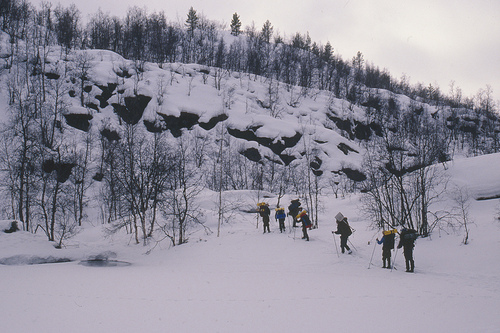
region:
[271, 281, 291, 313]
The snow is a very, very bright white color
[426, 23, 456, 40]
The sky is a rather dull gray color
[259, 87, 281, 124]
The rocks beneath the snow are dark brown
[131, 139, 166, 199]
The trees are a very deep brown color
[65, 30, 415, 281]
This whole photo was taken in Colorado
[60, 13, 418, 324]
This whole photo was taken in Denver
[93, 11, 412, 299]
This whole photo was taken in early afternoon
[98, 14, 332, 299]
These people signed up for this journey months ago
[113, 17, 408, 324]
Jackson Zeke is the man who took this photo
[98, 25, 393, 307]
This photo will soon appear in a tourist brochure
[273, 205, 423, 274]
these are people walking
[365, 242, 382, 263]
he is holding a stick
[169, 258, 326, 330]
the place is full of snow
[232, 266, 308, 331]
the snow is white in color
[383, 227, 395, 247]
he is carrying a bag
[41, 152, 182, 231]
the trees are dry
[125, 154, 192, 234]
the trees are thin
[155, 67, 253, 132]
the mountain is full of snow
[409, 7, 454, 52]
the sky is white in color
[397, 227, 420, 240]
the bag is big in size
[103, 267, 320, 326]
this is the ground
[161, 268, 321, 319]
the ground is full of snow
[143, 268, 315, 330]
this is the snow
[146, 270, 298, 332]
the snow is white in color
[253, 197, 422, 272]
these are some people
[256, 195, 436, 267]
the people are hiking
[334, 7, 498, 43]
this is the sky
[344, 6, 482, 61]
the sky is full of clouds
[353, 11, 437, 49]
the clouds are white in color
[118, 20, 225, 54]
these are several trees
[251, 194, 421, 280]
group of people skiing uphill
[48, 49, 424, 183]
snow covered rocks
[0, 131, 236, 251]
bare branched trees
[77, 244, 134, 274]
small circle of water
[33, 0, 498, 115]
white cloudy sky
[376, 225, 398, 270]
skier in black and yellow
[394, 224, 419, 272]
skier all in black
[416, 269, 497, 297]
marks in the snow from skiers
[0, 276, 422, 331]
flat snow covered ground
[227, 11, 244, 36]
pine tree on top of hill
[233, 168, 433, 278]
skiers traveling in a row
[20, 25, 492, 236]
snowy mountainside in back of skiers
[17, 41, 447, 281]
bare trees surrounding skiers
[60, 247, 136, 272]
small round pool of water in snow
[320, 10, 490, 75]
grey overcast sky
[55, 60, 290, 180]
dark surfaces of exposed rocks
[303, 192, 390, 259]
skier with white hat between others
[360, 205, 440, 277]
two skiers staying close to each other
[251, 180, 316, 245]
four skiers near top of hill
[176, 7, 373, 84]
evergreens lining top of mountain